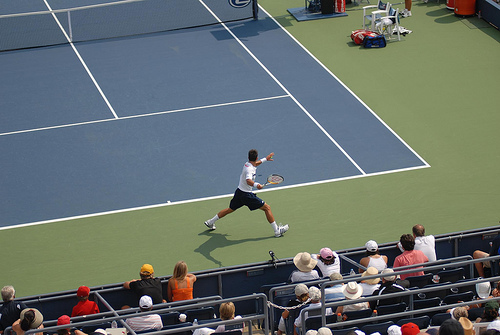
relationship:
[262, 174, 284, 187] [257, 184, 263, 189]
racket in mans hand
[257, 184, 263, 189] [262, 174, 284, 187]
hand with a racket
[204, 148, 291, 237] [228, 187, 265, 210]
guy with a pair of shorts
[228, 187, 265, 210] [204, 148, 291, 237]
shorts on guy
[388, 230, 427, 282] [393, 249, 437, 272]
spectator wearing shirt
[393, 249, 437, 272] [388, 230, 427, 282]
shirt on spectator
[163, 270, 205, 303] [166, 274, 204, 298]
girl wearing tank top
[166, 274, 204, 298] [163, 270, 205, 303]
tank top on girl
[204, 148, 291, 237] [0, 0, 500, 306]
guy on court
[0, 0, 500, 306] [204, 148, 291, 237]
court under guy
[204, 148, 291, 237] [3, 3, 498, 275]
guy on court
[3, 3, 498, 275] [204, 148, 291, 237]
court with guy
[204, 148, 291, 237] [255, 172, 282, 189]
guy holding racket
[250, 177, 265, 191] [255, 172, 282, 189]
hand holding racket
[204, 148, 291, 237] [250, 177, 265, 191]
guy with hand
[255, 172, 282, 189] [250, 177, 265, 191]
racket in hand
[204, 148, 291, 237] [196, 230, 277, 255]
guy in shadow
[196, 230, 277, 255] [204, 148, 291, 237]
shadow of a guy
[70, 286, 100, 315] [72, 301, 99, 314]
person wearing shirt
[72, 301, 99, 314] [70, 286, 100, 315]
shirt on person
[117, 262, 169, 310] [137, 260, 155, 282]
person wearing hat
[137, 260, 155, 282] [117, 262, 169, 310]
hat on person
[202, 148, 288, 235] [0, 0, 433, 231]
guy playing tennis on court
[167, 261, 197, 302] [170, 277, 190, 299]
girl in tanktop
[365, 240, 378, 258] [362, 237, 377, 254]
cap on head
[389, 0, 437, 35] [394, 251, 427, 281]
woman wearing shirt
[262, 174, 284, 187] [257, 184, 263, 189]
racket in hand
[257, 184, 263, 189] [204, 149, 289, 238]
hand of man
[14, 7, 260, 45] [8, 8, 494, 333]
net of court